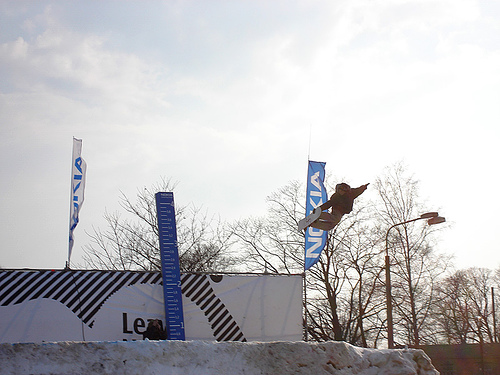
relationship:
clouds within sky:
[24, 23, 477, 158] [3, 1, 493, 285]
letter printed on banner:
[121, 310, 134, 333] [1, 269, 303, 341]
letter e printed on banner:
[132, 315, 147, 335] [1, 269, 303, 341]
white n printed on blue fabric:
[305, 237, 320, 258] [303, 159, 330, 266]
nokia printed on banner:
[62, 145, 99, 267] [63, 134, 87, 270]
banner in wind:
[64, 135, 90, 274] [11, 0, 483, 373]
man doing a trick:
[304, 181, 372, 232] [297, 181, 371, 231]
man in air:
[304, 181, 372, 232] [5, 11, 493, 360]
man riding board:
[302, 179, 372, 234] [297, 206, 322, 233]